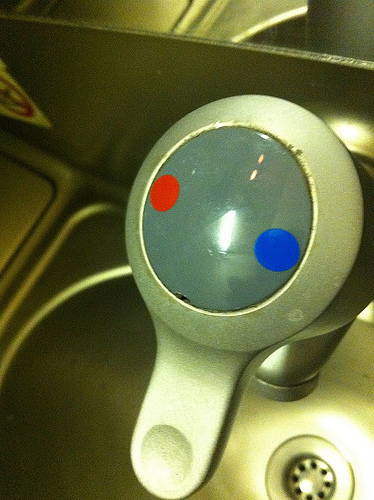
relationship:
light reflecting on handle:
[206, 207, 244, 260] [122, 93, 341, 374]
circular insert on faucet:
[140, 126, 312, 313] [116, 93, 372, 498]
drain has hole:
[252, 432, 323, 483] [308, 460, 318, 469]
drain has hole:
[252, 432, 323, 483] [318, 469, 326, 476]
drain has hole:
[252, 432, 323, 483] [325, 482, 332, 490]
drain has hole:
[252, 432, 323, 483] [317, 490, 326, 498]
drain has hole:
[252, 432, 323, 483] [288, 471, 300, 483]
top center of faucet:
[142, 127, 310, 314] [40, 90, 330, 490]